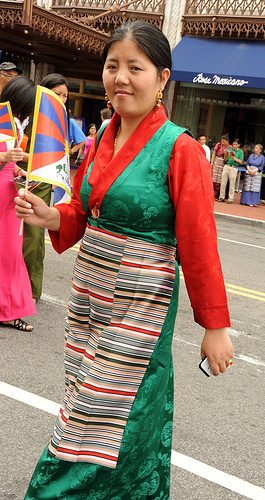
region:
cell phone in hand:
[196, 345, 221, 379]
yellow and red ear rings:
[156, 88, 163, 106]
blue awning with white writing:
[167, 31, 264, 94]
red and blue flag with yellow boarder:
[0, 103, 18, 142]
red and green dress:
[27, 112, 242, 498]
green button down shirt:
[223, 143, 242, 166]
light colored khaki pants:
[218, 160, 238, 201]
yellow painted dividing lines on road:
[35, 228, 264, 307]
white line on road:
[2, 371, 263, 497]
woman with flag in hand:
[15, 13, 248, 491]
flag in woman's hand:
[17, 83, 73, 232]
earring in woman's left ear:
[153, 91, 164, 112]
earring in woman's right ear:
[103, 91, 112, 109]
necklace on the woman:
[109, 124, 120, 156]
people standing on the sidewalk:
[215, 129, 264, 206]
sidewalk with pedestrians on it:
[220, 205, 260, 215]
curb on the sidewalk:
[217, 211, 250, 225]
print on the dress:
[142, 414, 165, 491]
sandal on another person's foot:
[0, 312, 36, 333]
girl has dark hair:
[111, 18, 166, 75]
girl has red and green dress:
[87, 118, 163, 469]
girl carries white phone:
[191, 354, 222, 380]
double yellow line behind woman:
[185, 267, 261, 305]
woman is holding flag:
[29, 106, 85, 207]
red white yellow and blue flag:
[32, 86, 85, 218]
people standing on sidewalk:
[202, 101, 261, 191]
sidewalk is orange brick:
[217, 198, 264, 225]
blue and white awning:
[181, 43, 263, 101]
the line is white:
[191, 444, 237, 495]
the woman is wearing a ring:
[221, 354, 236, 369]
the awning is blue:
[176, 36, 259, 91]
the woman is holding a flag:
[10, 14, 246, 493]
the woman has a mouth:
[108, 87, 139, 102]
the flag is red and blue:
[28, 73, 76, 198]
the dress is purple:
[240, 134, 264, 208]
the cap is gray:
[2, 60, 25, 74]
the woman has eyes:
[104, 60, 148, 73]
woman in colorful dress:
[12, 20, 229, 493]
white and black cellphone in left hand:
[198, 335, 234, 377]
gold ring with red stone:
[228, 360, 233, 365]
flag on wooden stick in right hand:
[10, 81, 77, 235]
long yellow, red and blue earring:
[154, 85, 166, 113]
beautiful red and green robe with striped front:
[20, 117, 229, 498]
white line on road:
[174, 448, 261, 497]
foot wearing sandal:
[3, 317, 31, 332]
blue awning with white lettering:
[170, 35, 262, 85]